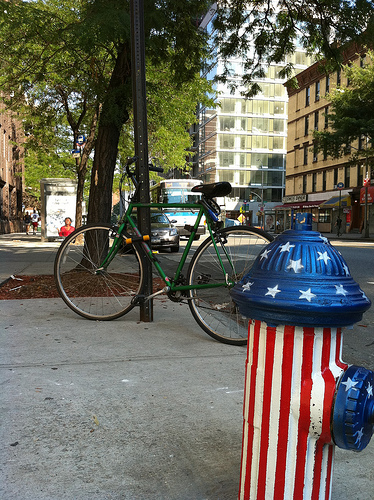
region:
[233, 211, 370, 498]
the fire hydrant is painted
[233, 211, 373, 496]
the fire hydrant has american flag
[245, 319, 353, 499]
the fire hydrant has red stripes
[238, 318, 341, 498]
the fire hydrant has white stripes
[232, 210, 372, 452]
the fire hydrant has white stars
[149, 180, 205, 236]
a bus is on the street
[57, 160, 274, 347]
the bike is green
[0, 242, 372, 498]
the sidewalk is dirty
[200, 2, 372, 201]
the building has many windows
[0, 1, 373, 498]
the scene takes place outdoors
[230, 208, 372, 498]
a hydrant painted like a flag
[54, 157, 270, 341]
a green bike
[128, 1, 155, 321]
a black metal pole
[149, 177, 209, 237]
a bus coming down the street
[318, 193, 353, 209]
a blue and yellow awning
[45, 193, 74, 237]
a sign with a woman on it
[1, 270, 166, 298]
brown mulch around a tree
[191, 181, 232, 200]
a black bike seat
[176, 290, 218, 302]
a bike kickstand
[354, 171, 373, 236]
a concrete sign pole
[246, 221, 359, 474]
red white and blue plug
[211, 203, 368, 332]
blue top of plug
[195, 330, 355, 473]
red and white stripes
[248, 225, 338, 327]
white stars on plug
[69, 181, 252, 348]
green bike behind plug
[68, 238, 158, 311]
bike has black tires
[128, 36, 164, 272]
bike near grey pole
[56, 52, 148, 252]
brown trunk on tree behind bike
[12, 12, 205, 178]
leafy tree in background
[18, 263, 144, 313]
red mulch around tree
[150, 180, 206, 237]
passenger bus on the road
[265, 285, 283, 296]
white star painted on the hydrant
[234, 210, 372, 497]
fire hydrant painted like an american flag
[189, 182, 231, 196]
black bicycle seat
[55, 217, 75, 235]
advertisement on the back of the truck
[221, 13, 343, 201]
windows covering side of the building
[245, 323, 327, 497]
red and white painted stripes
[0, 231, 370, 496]
concrete side walk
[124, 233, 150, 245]
bicycle security lock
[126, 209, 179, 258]
silver car parked on the street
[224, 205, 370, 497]
a red, white, and blue fire hydrant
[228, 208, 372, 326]
the top of a fire hydrant with white stars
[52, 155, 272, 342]
a bicycle leaning against a pole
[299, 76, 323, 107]
the windows of a building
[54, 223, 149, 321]
the wheel of a bicycle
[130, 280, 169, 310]
a pedal on a bicycle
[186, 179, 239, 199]
the seat of a bicycle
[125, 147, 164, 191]
the handlebars of a bicycle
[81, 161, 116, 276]
the trunk of a tree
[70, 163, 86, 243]
the trunk of a tree